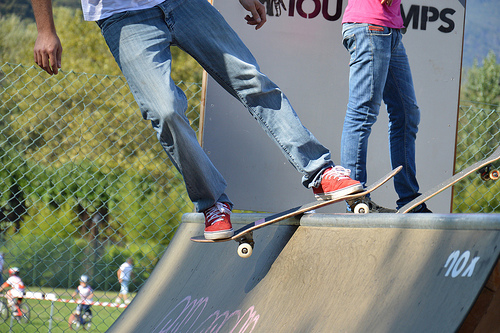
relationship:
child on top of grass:
[70, 274, 95, 323] [0, 286, 137, 332]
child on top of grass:
[0, 267, 25, 314] [0, 286, 137, 332]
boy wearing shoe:
[30, 0, 364, 241] [204, 201, 235, 240]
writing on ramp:
[152, 295, 259, 333] [105, 213, 500, 333]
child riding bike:
[70, 274, 95, 323] [68, 296, 92, 331]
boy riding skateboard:
[30, 0, 364, 241] [190, 165, 403, 258]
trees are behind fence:
[0, 0, 500, 291] [2, 233, 168, 292]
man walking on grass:
[116, 258, 133, 307] [0, 286, 137, 332]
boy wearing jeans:
[30, 0, 364, 241] [95, 0, 335, 212]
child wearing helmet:
[0, 267, 25, 314] [9, 266, 20, 276]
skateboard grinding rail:
[190, 165, 403, 258] [180, 212, 499, 231]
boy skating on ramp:
[30, 0, 364, 241] [105, 213, 500, 333]